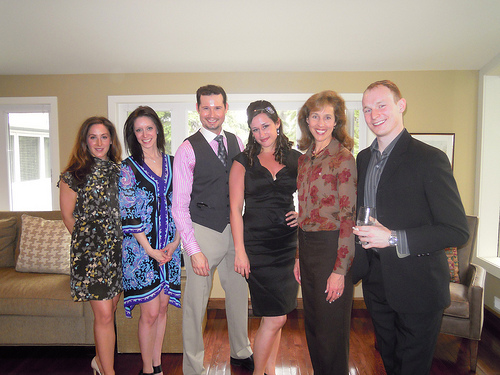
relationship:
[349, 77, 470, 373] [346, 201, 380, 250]
man holding glass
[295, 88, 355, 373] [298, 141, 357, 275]
person wearing blouse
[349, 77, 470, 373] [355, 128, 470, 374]
man wearing suit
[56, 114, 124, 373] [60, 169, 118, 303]
person in a dress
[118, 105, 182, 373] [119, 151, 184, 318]
person in a blue dress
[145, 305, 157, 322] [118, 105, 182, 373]
knees of a person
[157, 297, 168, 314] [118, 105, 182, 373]
knees of a person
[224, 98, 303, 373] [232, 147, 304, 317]
woman wearing a black dress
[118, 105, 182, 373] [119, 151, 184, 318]
person in blue dress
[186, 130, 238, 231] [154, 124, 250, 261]
suit vest over shirt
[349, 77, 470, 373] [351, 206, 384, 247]
man holding wine glass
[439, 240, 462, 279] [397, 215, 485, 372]
pillow on chair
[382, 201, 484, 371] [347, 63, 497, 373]
chair behind man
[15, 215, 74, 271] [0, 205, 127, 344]
pillow on couch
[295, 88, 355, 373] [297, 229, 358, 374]
person in pants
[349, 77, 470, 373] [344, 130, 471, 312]
man wearing suit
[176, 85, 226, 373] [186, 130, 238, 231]
man wearing suit vest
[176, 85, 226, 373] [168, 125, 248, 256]
man wearing long sleeve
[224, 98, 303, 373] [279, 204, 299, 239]
woman holding hip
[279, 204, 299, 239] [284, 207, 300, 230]
hip with hand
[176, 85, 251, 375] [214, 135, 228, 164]
man wearing tie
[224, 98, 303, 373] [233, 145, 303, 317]
woman wearing dress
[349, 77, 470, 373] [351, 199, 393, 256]
man holding glass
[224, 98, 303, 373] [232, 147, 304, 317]
woman wearing black dress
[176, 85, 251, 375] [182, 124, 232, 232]
man wearing vest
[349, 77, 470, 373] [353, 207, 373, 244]
man has drink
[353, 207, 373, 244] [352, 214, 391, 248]
drink in hand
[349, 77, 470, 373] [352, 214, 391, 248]
man has hand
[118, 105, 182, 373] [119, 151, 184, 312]
person wearing blue dress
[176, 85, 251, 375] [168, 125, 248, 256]
man wearing long sleeve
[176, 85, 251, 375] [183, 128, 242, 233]
man wearing vest